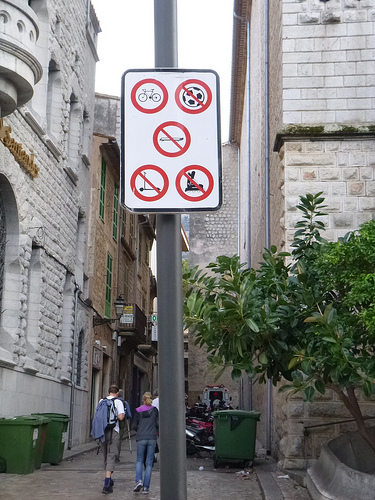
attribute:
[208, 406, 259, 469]
dumpster — green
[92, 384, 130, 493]
person — walking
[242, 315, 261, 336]
leaf — green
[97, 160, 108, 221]
shutter — green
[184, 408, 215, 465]
bike — allowed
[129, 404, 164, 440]
hoodie — grey, purple, black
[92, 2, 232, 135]
sky — hazy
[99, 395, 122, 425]
backpack — blue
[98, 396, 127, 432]
shirt — white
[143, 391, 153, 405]
hair — ponytail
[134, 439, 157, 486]
jeans — blue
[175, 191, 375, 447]
tree — tall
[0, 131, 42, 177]
writing — gold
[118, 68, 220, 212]
sign — red, informational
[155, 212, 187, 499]
pole — grey